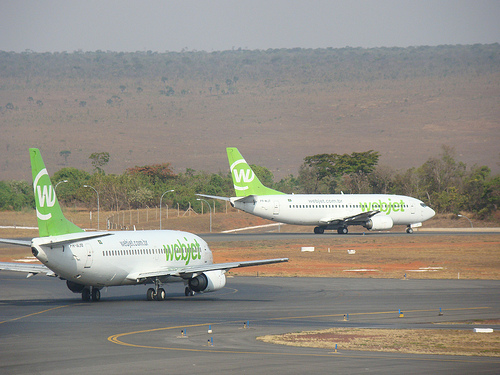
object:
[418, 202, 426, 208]
windshield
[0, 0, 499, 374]
airport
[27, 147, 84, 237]
tail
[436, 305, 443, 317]
blue marker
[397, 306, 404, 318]
blue marker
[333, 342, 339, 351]
blue marker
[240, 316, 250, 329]
blue marker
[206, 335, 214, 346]
blue marker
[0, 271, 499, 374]
tarmac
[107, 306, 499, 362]
lines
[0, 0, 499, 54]
sky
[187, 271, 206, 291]
jet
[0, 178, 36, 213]
trees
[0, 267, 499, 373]
ground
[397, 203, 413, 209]
windows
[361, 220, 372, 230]
jet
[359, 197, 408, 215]
lettering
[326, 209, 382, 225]
wing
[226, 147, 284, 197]
tail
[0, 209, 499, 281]
sand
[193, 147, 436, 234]
jetliner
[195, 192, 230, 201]
tail wing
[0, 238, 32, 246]
tail wing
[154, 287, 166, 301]
gear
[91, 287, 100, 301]
gear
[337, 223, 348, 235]
gear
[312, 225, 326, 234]
gear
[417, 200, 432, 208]
cock pit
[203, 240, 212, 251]
cock pit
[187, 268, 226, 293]
engine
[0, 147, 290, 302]
airplanes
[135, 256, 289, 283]
wing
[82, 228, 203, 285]
body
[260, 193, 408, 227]
body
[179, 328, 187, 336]
marker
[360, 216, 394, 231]
engine